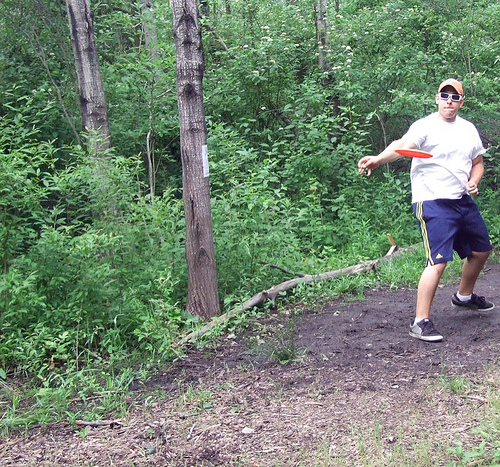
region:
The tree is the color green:
[10, 170, 149, 332]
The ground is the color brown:
[179, 369, 424, 456]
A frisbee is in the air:
[388, 137, 441, 167]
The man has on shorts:
[408, 189, 496, 270]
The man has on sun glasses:
[434, 88, 468, 108]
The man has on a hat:
[432, 66, 467, 106]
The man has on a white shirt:
[397, 105, 487, 205]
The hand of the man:
[355, 153, 381, 178]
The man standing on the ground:
[331, 63, 496, 359]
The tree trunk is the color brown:
[166, 13, 226, 331]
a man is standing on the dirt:
[338, 49, 495, 360]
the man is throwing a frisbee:
[345, 42, 487, 354]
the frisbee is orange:
[375, 131, 445, 193]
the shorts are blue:
[404, 189, 487, 286]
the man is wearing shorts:
[402, 188, 493, 278]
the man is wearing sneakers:
[392, 275, 497, 361]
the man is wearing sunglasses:
[423, 85, 475, 115]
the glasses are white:
[417, 70, 474, 121]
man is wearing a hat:
[423, 69, 467, 109]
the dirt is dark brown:
[328, 270, 478, 367]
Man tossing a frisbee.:
[355, 65, 487, 197]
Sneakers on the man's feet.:
[405, 282, 495, 349]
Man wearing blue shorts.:
[389, 188, 490, 270]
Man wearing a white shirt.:
[395, 109, 485, 216]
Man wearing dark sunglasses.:
[421, 71, 472, 123]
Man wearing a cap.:
[425, 74, 470, 101]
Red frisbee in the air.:
[395, 142, 447, 168]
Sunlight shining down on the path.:
[142, 375, 427, 464]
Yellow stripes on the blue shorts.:
[406, 179, 442, 280]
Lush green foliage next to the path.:
[13, 118, 147, 379]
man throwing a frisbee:
[353, 73, 497, 346]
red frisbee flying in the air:
[389, 143, 433, 161]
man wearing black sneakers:
[406, 285, 494, 345]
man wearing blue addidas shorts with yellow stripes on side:
[409, 191, 496, 266]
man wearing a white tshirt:
[401, 107, 485, 201]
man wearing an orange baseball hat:
[435, 73, 465, 96]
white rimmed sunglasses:
[438, 86, 467, 101]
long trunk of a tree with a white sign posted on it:
[166, 2, 223, 318]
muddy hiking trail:
[25, 265, 498, 464]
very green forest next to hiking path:
[2, 0, 498, 382]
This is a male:
[355, 68, 496, 340]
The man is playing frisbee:
[349, 64, 499, 344]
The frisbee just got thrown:
[382, 143, 444, 165]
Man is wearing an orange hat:
[427, 73, 472, 117]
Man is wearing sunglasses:
[431, 88, 465, 103]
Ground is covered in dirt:
[195, 288, 414, 464]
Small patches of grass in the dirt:
[194, 335, 310, 404]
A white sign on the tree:
[195, 130, 218, 187]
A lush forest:
[8, 0, 369, 325]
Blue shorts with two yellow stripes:
[405, 200, 499, 259]